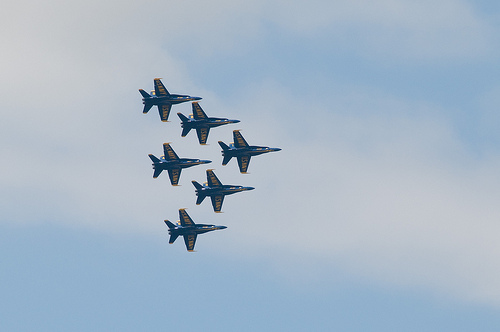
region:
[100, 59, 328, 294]
there are planes flying in the sky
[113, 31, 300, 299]
there are six planes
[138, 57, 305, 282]
six blue and yellow jets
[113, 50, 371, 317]
six yellow and blue jets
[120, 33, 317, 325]
the planes are in a triangle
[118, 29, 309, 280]
they are flying in formation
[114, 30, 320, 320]
the jets are flying in a triangle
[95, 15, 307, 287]
the jets are flying in formation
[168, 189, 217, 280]
the wings say "US NAVY"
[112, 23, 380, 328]
there are blue and yellow jet planes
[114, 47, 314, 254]
group of Blue Angel planes flying in the sky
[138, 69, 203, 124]
Left rear Blue Angel plane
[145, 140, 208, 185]
center rear blue angel plane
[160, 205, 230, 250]
right rear Blue Angel plane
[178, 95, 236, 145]
center left blue angel plane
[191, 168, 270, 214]
center right Blue angel plane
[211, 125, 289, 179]
lead blue angel plane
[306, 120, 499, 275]
wispy white clouds in the sky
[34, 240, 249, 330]
bright clear blue sky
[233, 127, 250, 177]
yellow writing on the blue plane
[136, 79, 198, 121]
airplane in the sky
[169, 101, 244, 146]
airplane in the sky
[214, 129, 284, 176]
airplane in the sky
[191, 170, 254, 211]
airplane in the sky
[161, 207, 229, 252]
airplane in the sky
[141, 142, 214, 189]
airplane in the sky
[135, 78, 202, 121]
blue airplane in the sky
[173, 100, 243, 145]
blue airplane in the sky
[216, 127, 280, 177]
blue airplane in the sky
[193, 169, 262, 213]
blue airplane in the sky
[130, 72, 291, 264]
Blue Angels Flying in Formation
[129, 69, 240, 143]
Two blue f-16s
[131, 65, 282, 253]
Six fighter jets flying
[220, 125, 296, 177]
Fighter Jet with Blue and Yellow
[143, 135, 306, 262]
Bottom half of flight formation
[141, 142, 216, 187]
F-16 flying in sky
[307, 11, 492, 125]
Very light white clouds in sky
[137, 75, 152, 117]
Tail section of fighter jet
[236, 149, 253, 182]
Words on underside of wing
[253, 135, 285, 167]
Front of fighter jet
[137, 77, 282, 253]
Blue jets in the sky.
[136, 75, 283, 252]
Blue planes in the sky.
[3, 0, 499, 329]
Clouds in the blue sky.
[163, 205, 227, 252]
A jet in the air.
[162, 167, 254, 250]
Two planes in the sky.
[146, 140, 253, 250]
Three jets in the sky.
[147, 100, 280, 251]
Five blue planes flying.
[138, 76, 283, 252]
Six planes flying in the sky.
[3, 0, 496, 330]
A white and blue sky.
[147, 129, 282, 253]
Four blue airplanes flying.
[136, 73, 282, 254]
A group of fighter jets in the sky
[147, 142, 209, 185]
A fighter jet surrounded by other fighter jets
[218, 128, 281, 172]
A fighter jet leading a group of jets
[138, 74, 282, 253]
A group of jets in the sky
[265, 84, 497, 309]
Hazy clouds above the group of jets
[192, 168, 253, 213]
A jet surrounded on all sides by other jets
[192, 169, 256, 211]
the grey and yellow fighter jet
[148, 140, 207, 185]
the grey and yellow fighter jet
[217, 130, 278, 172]
the grey and yellow fighter jet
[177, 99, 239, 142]
the grey and yellow fighter jet